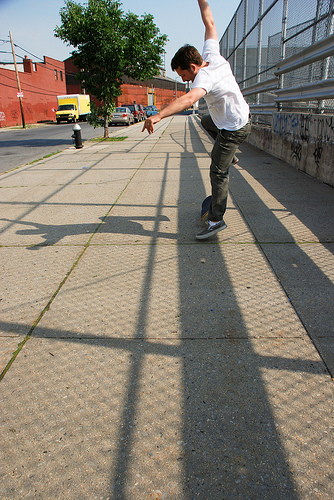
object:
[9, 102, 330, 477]
sidewalk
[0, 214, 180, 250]
shadow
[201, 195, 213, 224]
skateboarder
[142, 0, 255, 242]
boy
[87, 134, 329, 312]
sidewalk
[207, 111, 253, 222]
pants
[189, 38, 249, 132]
white shirt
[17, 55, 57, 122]
walls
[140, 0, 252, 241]
skater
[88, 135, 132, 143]
grass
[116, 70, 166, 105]
building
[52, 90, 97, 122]
truck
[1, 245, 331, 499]
sidewalk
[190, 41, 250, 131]
shirt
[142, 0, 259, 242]
man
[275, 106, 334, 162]
graffiti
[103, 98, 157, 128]
bear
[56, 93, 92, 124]
truck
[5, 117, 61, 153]
street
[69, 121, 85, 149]
fire hydrant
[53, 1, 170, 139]
tree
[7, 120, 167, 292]
sidewalk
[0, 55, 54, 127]
building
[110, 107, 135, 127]
cars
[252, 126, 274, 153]
wall